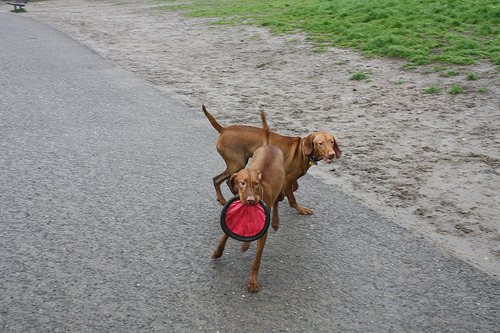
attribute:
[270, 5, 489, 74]
grass — short, green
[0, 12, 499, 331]
asphalt — gray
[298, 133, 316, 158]
ear — large, floppy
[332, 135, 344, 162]
ear — large, floppy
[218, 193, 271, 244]
ring — black